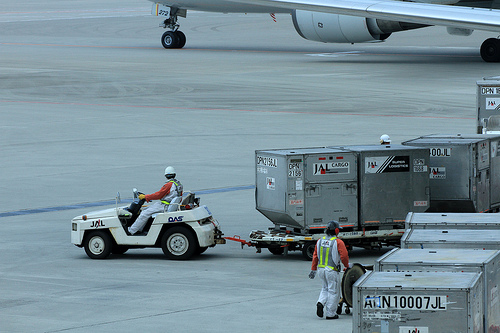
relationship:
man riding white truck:
[70, 163, 218, 259] [71, 193, 220, 260]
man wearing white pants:
[125, 166, 184, 236] [128, 200, 167, 235]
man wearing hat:
[125, 166, 184, 236] [164, 166, 176, 176]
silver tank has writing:
[353, 270, 484, 332] [380, 295, 446, 309]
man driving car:
[125, 166, 184, 236] [71, 193, 220, 260]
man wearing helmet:
[125, 166, 184, 236] [164, 166, 176, 176]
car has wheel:
[71, 193, 220, 260] [159, 224, 196, 259]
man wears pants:
[125, 166, 184, 236] [128, 200, 167, 235]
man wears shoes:
[308, 219, 350, 320] [316, 302, 325, 320]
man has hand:
[308, 219, 350, 320] [308, 270, 318, 279]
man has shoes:
[308, 219, 350, 320] [316, 302, 325, 320]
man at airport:
[308, 219, 350, 320] [7, 0, 499, 330]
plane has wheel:
[177, 0, 499, 61] [160, 29, 187, 50]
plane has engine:
[177, 0, 499, 61] [290, 9, 442, 42]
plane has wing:
[177, 0, 499, 61] [260, 0, 498, 34]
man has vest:
[308, 219, 350, 320] [316, 235, 342, 271]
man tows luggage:
[125, 166, 184, 236] [247, 128, 499, 241]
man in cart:
[125, 166, 184, 236] [71, 193, 220, 260]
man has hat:
[125, 166, 184, 236] [164, 166, 176, 176]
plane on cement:
[177, 0, 499, 61] [2, 1, 499, 76]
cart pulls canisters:
[71, 193, 220, 260] [247, 128, 499, 241]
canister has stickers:
[353, 270, 484, 332] [380, 295, 446, 309]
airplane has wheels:
[177, 0, 499, 61] [160, 29, 187, 50]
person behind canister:
[378, 134, 393, 146] [328, 144, 433, 228]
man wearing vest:
[308, 219, 350, 320] [316, 235, 342, 271]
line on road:
[2, 181, 254, 216] [13, 20, 459, 330]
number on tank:
[380, 295, 446, 309] [347, 210, 497, 330]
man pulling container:
[125, 166, 184, 236] [255, 147, 358, 232]